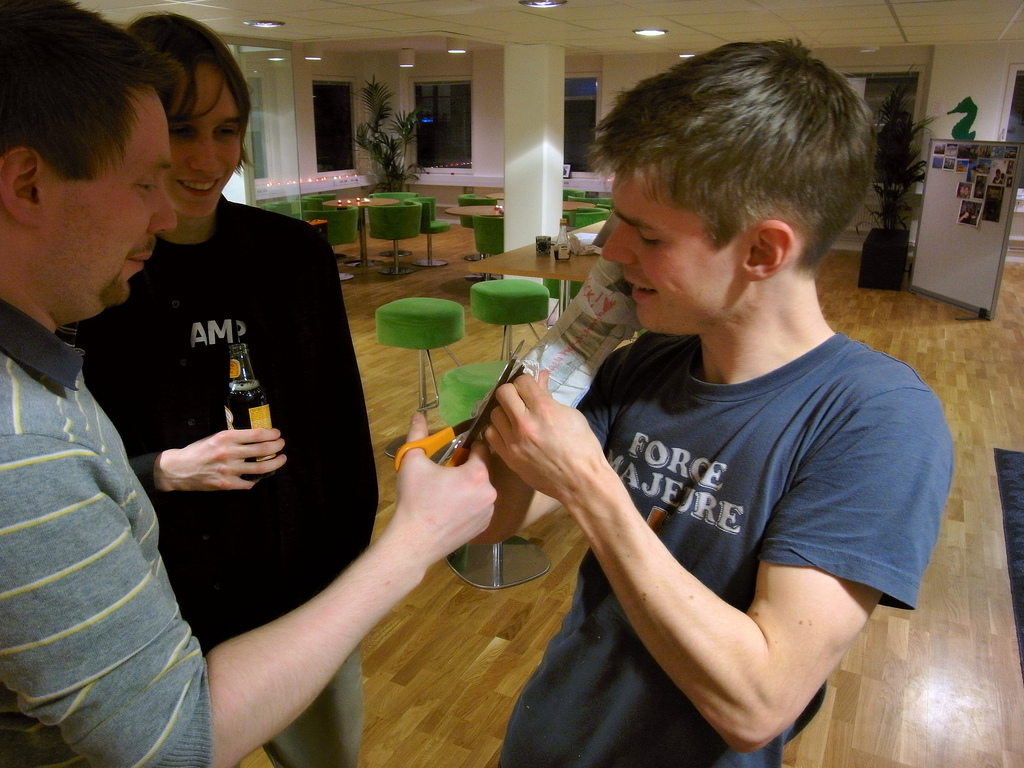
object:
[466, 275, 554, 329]
seat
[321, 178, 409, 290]
table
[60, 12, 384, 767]
person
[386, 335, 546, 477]
scissors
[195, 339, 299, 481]
bottle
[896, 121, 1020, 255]
pictures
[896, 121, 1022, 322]
board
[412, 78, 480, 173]
window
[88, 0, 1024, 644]
room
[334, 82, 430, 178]
plant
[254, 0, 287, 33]
light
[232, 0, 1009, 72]
ceiling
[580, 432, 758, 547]
writing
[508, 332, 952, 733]
shirt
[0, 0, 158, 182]
haircut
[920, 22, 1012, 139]
wall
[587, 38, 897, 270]
head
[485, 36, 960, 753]
boy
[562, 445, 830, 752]
arm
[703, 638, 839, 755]
elbow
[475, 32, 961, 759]
man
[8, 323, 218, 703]
shirt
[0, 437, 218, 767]
lines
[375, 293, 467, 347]
cushion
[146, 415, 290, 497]
hand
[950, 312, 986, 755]
floor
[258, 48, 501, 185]
wall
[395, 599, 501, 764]
wooden floor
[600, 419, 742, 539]
design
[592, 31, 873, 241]
hair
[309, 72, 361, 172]
windows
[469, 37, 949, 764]
standing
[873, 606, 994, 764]
wooden floor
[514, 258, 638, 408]
cast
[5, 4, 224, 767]
man